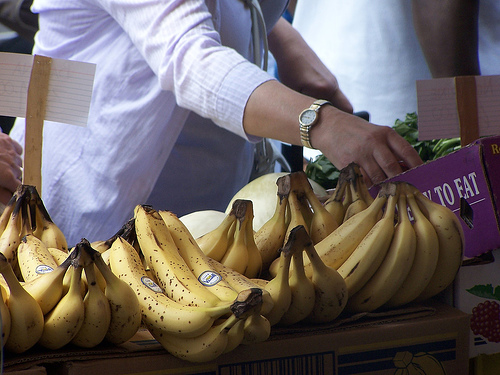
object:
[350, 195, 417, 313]
bananas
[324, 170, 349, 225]
bananas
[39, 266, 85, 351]
bananas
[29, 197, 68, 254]
bananas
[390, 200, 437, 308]
yellow bananas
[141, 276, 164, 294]
sticker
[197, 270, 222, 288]
sticker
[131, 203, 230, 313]
banana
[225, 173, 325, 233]
melon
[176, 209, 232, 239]
melon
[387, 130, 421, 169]
index finger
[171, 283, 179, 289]
spots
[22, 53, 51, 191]
stick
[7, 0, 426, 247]
man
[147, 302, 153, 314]
spot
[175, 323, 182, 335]
spot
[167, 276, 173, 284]
spot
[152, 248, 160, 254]
spot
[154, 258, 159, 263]
spot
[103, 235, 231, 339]
banana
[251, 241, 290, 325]
banana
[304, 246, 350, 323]
banana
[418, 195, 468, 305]
banana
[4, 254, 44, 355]
bananas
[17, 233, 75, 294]
bananas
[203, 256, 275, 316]
banana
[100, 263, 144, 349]
banana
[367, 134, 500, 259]
box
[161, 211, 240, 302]
banana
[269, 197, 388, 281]
bananas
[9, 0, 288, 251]
shirt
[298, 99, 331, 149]
watch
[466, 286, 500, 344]
berries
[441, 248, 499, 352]
box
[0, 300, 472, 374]
box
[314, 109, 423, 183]
hand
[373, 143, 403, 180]
middle finger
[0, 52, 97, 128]
sign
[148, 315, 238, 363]
banana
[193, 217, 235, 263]
banana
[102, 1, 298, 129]
arm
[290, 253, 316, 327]
banana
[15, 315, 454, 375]
table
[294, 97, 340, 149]
man's wrist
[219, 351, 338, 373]
barcode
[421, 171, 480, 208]
text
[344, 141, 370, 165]
knuckle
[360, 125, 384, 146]
knuckle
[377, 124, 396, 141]
knuckle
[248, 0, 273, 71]
tie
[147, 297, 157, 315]
mark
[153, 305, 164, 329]
mark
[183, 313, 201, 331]
mark